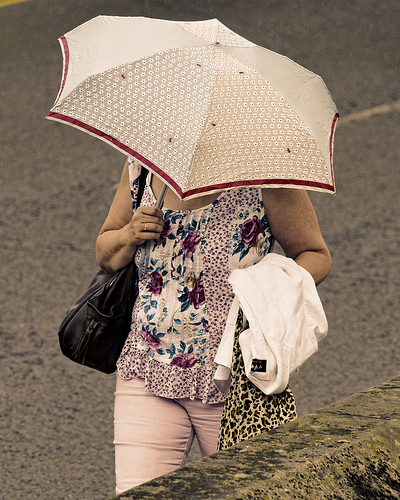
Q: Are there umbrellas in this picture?
A: Yes, there is an umbrella.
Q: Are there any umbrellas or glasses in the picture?
A: Yes, there is an umbrella.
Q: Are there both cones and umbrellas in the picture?
A: No, there is an umbrella but no cones.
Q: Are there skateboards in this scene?
A: No, there are no skateboards.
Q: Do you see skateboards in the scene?
A: No, there are no skateboards.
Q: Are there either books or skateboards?
A: No, there are no skateboards or books.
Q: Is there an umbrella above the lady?
A: Yes, there is an umbrella above the lady.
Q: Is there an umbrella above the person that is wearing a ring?
A: Yes, there is an umbrella above the lady.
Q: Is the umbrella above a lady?
A: Yes, the umbrella is above a lady.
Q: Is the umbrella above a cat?
A: No, the umbrella is above a lady.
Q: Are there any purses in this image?
A: Yes, there is a purse.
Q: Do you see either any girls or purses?
A: Yes, there is a purse.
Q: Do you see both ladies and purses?
A: Yes, there are both a purse and a lady.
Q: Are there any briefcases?
A: No, there are no briefcases.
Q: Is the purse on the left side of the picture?
A: Yes, the purse is on the left of the image.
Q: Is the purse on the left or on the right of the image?
A: The purse is on the left of the image.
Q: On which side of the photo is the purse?
A: The purse is on the left of the image.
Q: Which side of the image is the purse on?
A: The purse is on the left of the image.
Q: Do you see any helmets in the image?
A: No, there are no helmets.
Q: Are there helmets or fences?
A: No, there are no helmets or fences.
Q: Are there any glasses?
A: No, there are no glasses.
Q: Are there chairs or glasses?
A: No, there are no glasses or chairs.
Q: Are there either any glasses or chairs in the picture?
A: No, there are no glasses or chairs.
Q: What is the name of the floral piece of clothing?
A: The clothing item is a blouse.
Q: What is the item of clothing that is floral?
A: The clothing item is a blouse.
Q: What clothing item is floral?
A: The clothing item is a blouse.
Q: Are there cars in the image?
A: No, there are no cars.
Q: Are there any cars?
A: No, there are no cars.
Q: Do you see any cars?
A: No, there are no cars.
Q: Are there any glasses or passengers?
A: No, there are no glasses or passengers.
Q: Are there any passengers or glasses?
A: No, there are no glasses or passengers.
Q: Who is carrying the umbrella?
A: The lady is carrying the umbrella.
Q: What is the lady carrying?
A: The lady is carrying an umbrella.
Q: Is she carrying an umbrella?
A: Yes, the lady is carrying an umbrella.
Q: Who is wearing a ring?
A: The lady is wearing a ring.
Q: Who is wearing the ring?
A: The lady is wearing a ring.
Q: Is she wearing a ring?
A: Yes, the lady is wearing a ring.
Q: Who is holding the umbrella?
A: The lady is holding the umbrella.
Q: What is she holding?
A: The lady is holding the umbrella.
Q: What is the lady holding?
A: The lady is holding the umbrella.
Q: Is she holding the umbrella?
A: Yes, the lady is holding the umbrella.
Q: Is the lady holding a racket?
A: No, the lady is holding the umbrella.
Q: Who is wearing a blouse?
A: The lady is wearing a blouse.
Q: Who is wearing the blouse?
A: The lady is wearing a blouse.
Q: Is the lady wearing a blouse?
A: Yes, the lady is wearing a blouse.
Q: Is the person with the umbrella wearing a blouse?
A: Yes, the lady is wearing a blouse.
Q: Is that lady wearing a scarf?
A: No, the lady is wearing a blouse.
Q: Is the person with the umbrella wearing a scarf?
A: No, the lady is wearing a blouse.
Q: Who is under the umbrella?
A: The lady is under the umbrella.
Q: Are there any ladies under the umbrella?
A: Yes, there is a lady under the umbrella.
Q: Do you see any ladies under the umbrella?
A: Yes, there is a lady under the umbrella.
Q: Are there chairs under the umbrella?
A: No, there is a lady under the umbrella.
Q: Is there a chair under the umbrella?
A: No, there is a lady under the umbrella.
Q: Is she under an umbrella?
A: Yes, the lady is under an umbrella.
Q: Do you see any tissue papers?
A: No, there are no tissue papers.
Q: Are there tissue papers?
A: No, there are no tissue papers.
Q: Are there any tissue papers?
A: No, there are no tissue papers.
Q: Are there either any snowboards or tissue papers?
A: No, there are no tissue papers or snowboards.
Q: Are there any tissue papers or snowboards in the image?
A: No, there are no tissue papers or snowboards.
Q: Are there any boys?
A: No, there are no boys.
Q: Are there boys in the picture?
A: No, there are no boys.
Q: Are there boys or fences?
A: No, there are no boys or fences.